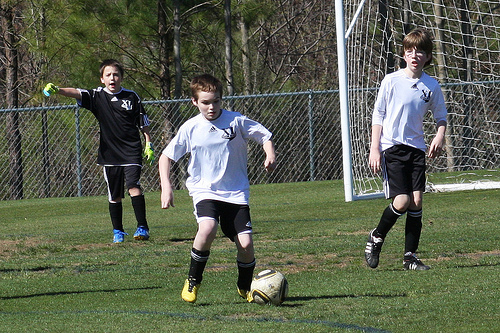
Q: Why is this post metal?
A: Durable.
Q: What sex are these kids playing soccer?
A: Male.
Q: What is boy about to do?
A: Kick ball.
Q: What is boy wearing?
A: Uniform.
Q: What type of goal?
A: Soccer.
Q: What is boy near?
A: Soccer ball.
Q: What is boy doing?
A: Yelling.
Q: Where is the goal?
A: Behind player.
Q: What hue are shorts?
A: Black.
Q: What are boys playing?
A: Soccer.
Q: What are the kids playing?
A: Soccer.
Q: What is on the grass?
A: A ball.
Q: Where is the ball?
A: On the grass.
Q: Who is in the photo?
A: Some kids.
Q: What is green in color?
A: The grass.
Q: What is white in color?
A: The goal post.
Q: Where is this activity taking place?
A: A soccer field.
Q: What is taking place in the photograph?
A: A soccer game.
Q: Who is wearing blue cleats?
A: The boy on the left.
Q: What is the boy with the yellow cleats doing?
A: Kicking the ball.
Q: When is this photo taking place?
A: Daytime.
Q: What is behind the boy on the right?
A: A net.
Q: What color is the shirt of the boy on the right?
A: White.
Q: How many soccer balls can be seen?
A: One.